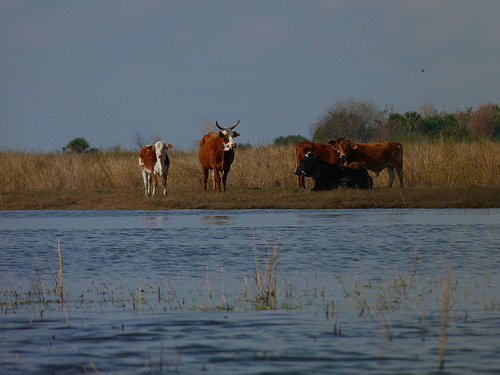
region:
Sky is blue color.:
[20, 31, 317, 91]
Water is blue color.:
[98, 226, 243, 254]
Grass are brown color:
[12, 155, 112, 185]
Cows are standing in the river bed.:
[120, 125, 390, 190]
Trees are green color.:
[360, 100, 465, 135]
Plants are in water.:
[25, 255, 476, 347]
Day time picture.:
[7, 17, 478, 362]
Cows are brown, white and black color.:
[122, 112, 373, 188]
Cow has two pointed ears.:
[213, 127, 243, 142]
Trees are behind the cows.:
[254, 76, 487, 152]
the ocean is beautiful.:
[107, 208, 399, 353]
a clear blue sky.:
[60, 17, 290, 87]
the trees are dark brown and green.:
[311, 105, 492, 140]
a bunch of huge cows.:
[56, 75, 468, 200]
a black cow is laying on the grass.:
[295, 145, 375, 202]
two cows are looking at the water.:
[121, 110, 247, 195]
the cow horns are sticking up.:
[211, 116, 236, 126]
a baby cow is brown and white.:
[125, 130, 180, 195]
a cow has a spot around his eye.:
[216, 125, 226, 145]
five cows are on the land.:
[22, 7, 482, 199]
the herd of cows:
[137, 112, 407, 194]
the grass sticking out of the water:
[17, 248, 460, 364]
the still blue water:
[72, 207, 432, 278]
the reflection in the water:
[136, 211, 348, 231]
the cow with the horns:
[192, 115, 245, 189]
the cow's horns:
[212, 119, 241, 131]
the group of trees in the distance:
[290, 94, 499, 154]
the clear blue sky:
[40, 22, 287, 117]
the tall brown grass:
[9, 155, 114, 196]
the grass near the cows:
[167, 190, 315, 207]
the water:
[158, 242, 226, 304]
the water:
[184, 251, 237, 329]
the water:
[248, 302, 274, 359]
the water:
[240, 274, 288, 363]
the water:
[252, 260, 274, 300]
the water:
[222, 224, 247, 267]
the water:
[192, 210, 264, 362]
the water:
[211, 226, 278, 324]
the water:
[225, 200, 317, 371]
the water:
[227, 251, 272, 333]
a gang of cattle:
[115, 105, 420, 201]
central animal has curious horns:
[186, 115, 246, 195]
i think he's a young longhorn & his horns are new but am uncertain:
[195, 110, 245, 135]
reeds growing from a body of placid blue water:
[0, 225, 496, 370]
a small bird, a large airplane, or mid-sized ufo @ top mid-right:
[415, 65, 425, 75]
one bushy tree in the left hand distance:
[55, 135, 105, 155]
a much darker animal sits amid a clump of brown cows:
[287, 146, 377, 196]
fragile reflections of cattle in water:
[129, 208, 413, 233]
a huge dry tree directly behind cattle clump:
[301, 93, 391, 150]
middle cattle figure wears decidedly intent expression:
[209, 128, 242, 154]